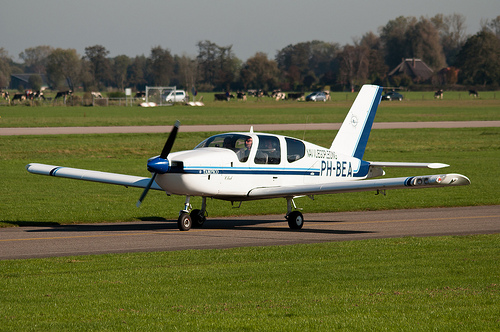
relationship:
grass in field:
[0, 230, 497, 330] [0, 88, 497, 330]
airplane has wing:
[24, 83, 470, 232] [25, 161, 163, 195]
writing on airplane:
[306, 145, 336, 160] [24, 83, 470, 232]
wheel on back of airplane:
[285, 206, 305, 231] [24, 83, 470, 232]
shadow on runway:
[0, 215, 380, 234] [0, 204, 499, 258]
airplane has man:
[24, 83, 470, 232] [236, 134, 254, 161]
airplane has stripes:
[30, 83, 470, 231] [181, 166, 357, 178]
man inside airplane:
[236, 134, 254, 161] [24, 83, 470, 232]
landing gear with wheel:
[281, 194, 307, 231] [285, 209, 305, 231]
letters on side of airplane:
[318, 158, 353, 178] [24, 83, 470, 232]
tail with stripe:
[328, 82, 384, 158] [356, 85, 378, 155]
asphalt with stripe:
[37, 223, 166, 252] [3, 230, 88, 242]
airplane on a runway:
[24, 83, 470, 232] [6, 203, 481, 255]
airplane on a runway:
[24, 83, 470, 232] [9, 206, 464, 246]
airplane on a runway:
[30, 83, 470, 231] [3, 200, 475, 243]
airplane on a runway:
[30, 83, 470, 231] [14, 209, 464, 249]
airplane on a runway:
[24, 83, 470, 232] [14, 209, 464, 249]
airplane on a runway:
[30, 83, 470, 231] [9, 206, 464, 246]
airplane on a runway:
[30, 83, 470, 231] [3, 207, 465, 254]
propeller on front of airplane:
[136, 120, 181, 203] [24, 83, 470, 232]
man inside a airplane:
[242, 134, 253, 159] [24, 83, 470, 232]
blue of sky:
[2, 0, 356, 35] [0, 1, 478, 84]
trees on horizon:
[236, 50, 283, 101] [6, 6, 483, 96]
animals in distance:
[14, 81, 291, 107] [15, 51, 480, 109]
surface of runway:
[67, 222, 137, 252] [1, 208, 421, 255]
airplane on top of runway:
[24, 83, 470, 232] [16, 200, 478, 257]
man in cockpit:
[236, 134, 254, 161] [202, 132, 280, 167]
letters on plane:
[303, 145, 376, 192] [60, 90, 463, 237]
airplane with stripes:
[24, 83, 470, 232] [191, 148, 311, 184]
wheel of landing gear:
[285, 209, 305, 231] [281, 194, 304, 230]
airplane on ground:
[24, 83, 470, 232] [184, 232, 374, 308]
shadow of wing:
[0, 215, 380, 234] [248, 172, 470, 204]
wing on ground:
[248, 172, 470, 204] [296, 241, 454, 294]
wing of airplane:
[310, 168, 461, 201] [49, 82, 465, 283]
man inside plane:
[236, 134, 254, 161] [30, 86, 483, 247]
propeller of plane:
[136, 120, 181, 203] [39, 74, 466, 247]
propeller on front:
[136, 120, 181, 203] [99, 115, 255, 245]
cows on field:
[8, 58, 108, 137] [3, 100, 161, 147]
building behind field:
[382, 57, 432, 89] [389, 87, 482, 130]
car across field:
[130, 77, 212, 123] [151, 96, 275, 136]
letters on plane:
[314, 160, 378, 191] [84, 75, 464, 247]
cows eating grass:
[6, 86, 481, 105] [0, 90, 499, 129]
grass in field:
[0, 90, 499, 129] [0, 88, 497, 330]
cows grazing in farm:
[6, 87, 480, 108] [2, 85, 494, 125]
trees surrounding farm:
[3, 15, 497, 92] [2, 85, 494, 125]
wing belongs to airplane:
[248, 172, 470, 204] [30, 83, 470, 231]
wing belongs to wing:
[24, 157, 164, 194] [248, 172, 470, 204]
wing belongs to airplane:
[24, 157, 164, 194] [30, 83, 470, 231]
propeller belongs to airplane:
[132, 117, 186, 209] [23, 78, 475, 239]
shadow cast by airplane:
[2, 212, 382, 234] [23, 78, 475, 239]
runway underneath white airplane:
[6, 205, 484, 244] [30, 83, 470, 231]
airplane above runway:
[30, 83, 470, 231] [4, 200, 484, 250]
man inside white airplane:
[236, 134, 254, 161] [30, 83, 470, 231]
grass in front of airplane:
[0, 230, 497, 330] [30, 83, 470, 231]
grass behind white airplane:
[0, 126, 498, 227] [30, 83, 470, 231]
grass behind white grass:
[0, 90, 499, 129] [2, 252, 484, 326]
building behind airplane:
[379, 50, 436, 90] [30, 83, 470, 231]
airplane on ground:
[24, 83, 470, 232] [4, 100, 484, 328]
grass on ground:
[0, 230, 499, 331] [4, 100, 484, 328]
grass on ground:
[3, 138, 483, 189] [4, 100, 484, 328]